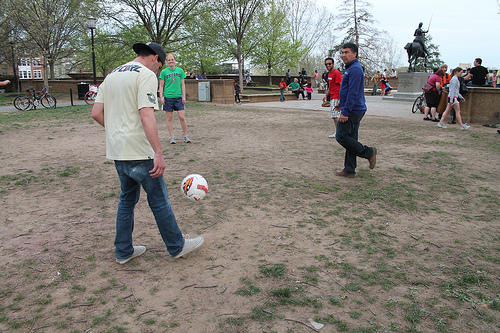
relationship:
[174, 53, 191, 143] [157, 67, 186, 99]
person wearing shirt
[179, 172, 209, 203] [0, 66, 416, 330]
ball in park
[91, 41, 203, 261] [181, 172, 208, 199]
guy with ball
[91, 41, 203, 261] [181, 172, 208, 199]
guy kicked ball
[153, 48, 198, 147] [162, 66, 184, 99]
soccer player wearing shirt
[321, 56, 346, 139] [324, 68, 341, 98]
man wearing t-shirt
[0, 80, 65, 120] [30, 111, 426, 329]
bicycles parked at edge of area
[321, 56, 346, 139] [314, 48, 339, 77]
man wearing sunglasses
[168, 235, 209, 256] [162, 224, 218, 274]
shoe on foot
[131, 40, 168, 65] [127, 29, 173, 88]
hat on head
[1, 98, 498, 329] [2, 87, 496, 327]
dirt on ground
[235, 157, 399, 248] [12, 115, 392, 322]
grass on ground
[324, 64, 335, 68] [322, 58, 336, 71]
glasses on face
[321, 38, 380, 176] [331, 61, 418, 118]
man wearing blue shirt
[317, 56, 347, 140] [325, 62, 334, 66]
man wearing glasses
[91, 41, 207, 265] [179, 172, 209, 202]
guy kicking ball